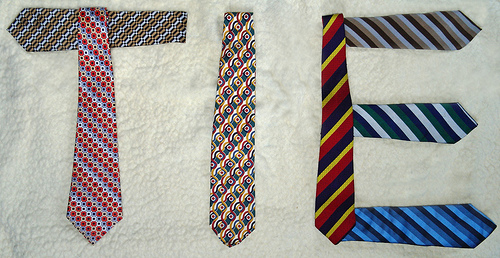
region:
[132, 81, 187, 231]
a cotton white blanket.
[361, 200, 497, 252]
a blue and black striped tie.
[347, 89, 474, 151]
a green blue and white striped tie.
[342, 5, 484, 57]
a brown blue and light brown striped tie.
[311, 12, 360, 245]
a red blue and yellow striped tie.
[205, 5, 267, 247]
a green yellow red and white designed tie.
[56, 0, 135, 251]
a red white and blue tie.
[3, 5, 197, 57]
a black blue white and gold tie.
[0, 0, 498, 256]
the letters spell tie.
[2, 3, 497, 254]
a picture of ties spelling the word tie.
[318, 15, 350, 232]
yellow, red and blue tie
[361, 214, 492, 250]
tie is hortizontal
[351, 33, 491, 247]
three ties on their side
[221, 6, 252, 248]
paisley colored tie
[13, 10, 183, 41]
tie is under another tie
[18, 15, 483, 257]
seven ties in photo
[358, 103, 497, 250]
two blue and black ties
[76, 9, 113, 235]
ties is covered in red dots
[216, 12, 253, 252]
tie stands alone in picture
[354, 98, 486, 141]
tie in middle is blue and green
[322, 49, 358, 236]
the tie has red and blue stripes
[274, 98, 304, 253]
the surace is cotton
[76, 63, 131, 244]
the tie is red and blue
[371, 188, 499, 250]
the tie has blue and black stripes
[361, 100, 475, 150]
the tie has green and white stripes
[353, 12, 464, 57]
the tie is brown and grey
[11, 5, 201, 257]
the tie has a t sign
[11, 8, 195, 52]
the tie is brown and white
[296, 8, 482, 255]
the letter is E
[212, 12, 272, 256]
THE LETTER IS I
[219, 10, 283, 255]
the letter is i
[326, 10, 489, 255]
the letter is e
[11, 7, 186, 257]
the letter is t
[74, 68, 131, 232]
the tie has red and blue circles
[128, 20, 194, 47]
the tie is brown and grey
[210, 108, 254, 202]
the tie is red and blue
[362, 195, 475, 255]
the tie has black and blue strips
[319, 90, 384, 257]
the tie has yellow and blue strips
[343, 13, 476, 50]
the tie is grey and purple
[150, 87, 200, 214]
the surface is white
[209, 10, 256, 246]
a green red and yellow neck tie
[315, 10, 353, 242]
a red, blue and yellow striped neck tie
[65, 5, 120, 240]
a red, blue and white polka dot neck tie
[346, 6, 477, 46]
a blue and brown neck tie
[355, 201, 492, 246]
a blue striped neck tie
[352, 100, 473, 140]
a green and blue striped neck tie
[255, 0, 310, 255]
a wool display cover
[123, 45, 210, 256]
a thick cotton sheet cover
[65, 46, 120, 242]
a silk neck tie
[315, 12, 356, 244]
a polyester neck tie